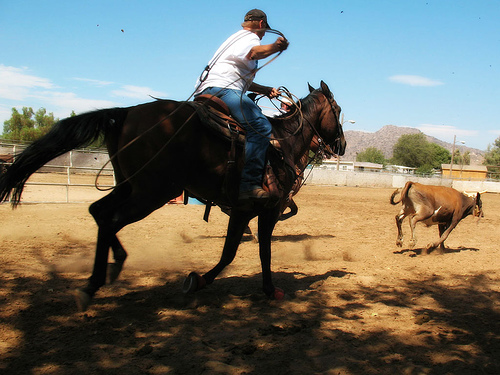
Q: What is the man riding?
A: A horse.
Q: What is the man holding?
A: A rope.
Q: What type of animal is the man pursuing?
A: A cow.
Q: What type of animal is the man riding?
A: A horse.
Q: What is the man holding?
A: A rope.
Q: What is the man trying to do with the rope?
A: Lasso the cow.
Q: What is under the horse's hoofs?
A: The dirt.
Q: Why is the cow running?
A: To avoid being lassoed.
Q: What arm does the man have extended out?
A: The right arm.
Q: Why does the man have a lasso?
A: To catch the cow.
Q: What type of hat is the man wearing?
A: A cap.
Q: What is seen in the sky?
A: Clouds.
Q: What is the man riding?
A: A horse.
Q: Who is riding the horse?
A: A man in a white shirt.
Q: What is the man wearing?
A: A white shirt.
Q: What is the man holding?
A: A rope.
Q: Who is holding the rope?
A: The man on the horse.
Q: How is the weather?
A: Partly cloudy.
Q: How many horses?
A: 1.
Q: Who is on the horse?
A: The man.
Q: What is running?
A: The calf.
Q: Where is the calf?
A: Ahead of the horse.